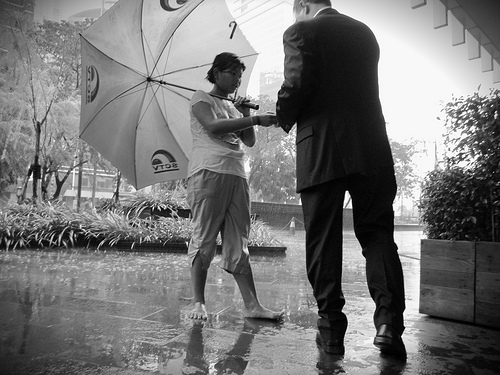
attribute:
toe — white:
[274, 311, 284, 323]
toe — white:
[191, 309, 201, 327]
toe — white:
[201, 313, 205, 320]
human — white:
[182, 52, 295, 334]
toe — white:
[188, 310, 198, 319]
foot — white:
[179, 288, 212, 325]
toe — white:
[202, 309, 211, 323]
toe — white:
[197, 314, 202, 323]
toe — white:
[194, 311, 200, 321]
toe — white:
[189, 310, 194, 321]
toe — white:
[185, 313, 193, 320]